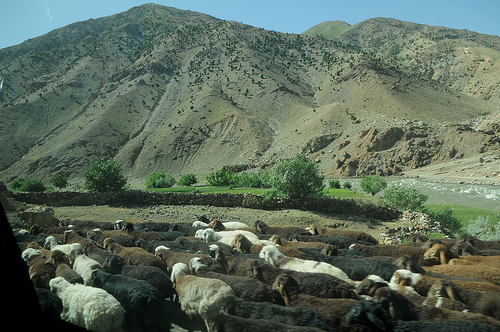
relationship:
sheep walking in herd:
[48, 272, 125, 329] [4, 217, 497, 329]